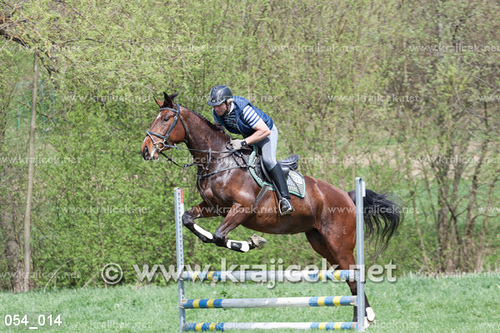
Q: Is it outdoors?
A: Yes, it is outdoors.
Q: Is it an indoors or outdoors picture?
A: It is outdoors.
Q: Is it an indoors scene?
A: No, it is outdoors.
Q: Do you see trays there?
A: No, there are no trays.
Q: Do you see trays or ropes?
A: No, there are no trays or ropes.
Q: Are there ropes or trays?
A: No, there are no trays or ropes.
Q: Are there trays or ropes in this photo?
A: No, there are no trays or ropes.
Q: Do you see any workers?
A: No, there are no workers.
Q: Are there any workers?
A: No, there are no workers.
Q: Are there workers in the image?
A: No, there are no workers.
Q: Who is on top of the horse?
A: The man is on top of the horse.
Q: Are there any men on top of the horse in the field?
A: Yes, there is a man on top of the horse.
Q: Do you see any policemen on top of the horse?
A: No, there is a man on top of the horse.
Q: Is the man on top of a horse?
A: Yes, the man is on top of a horse.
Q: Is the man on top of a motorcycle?
A: No, the man is on top of a horse.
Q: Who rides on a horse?
A: The man rides on a horse.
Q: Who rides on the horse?
A: The man rides on a horse.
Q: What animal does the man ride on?
A: The man rides on a horse.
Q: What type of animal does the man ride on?
A: The man rides on a horse.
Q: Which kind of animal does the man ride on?
A: The man rides on a horse.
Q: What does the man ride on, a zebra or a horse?
A: The man rides on a horse.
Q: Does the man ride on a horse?
A: Yes, the man rides on a horse.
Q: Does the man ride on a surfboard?
A: No, the man rides on a horse.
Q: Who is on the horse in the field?
A: The man is on the horse.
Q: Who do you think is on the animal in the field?
A: The man is on the horse.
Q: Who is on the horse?
A: The man is on the horse.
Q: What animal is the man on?
A: The man is on the horse.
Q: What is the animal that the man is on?
A: The animal is a horse.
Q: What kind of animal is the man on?
A: The man is on the horse.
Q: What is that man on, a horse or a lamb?
A: The man is on a horse.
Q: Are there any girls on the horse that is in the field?
A: No, there is a man on the horse.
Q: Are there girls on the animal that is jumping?
A: No, there is a man on the horse.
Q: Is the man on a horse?
A: Yes, the man is on a horse.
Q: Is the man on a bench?
A: No, the man is on a horse.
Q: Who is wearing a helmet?
A: The man is wearing a helmet.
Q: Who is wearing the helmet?
A: The man is wearing a helmet.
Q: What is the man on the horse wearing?
A: The man is wearing a helmet.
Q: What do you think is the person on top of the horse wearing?
A: The man is wearing a helmet.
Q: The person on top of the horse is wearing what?
A: The man is wearing a helmet.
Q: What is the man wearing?
A: The man is wearing a helmet.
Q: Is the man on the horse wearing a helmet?
A: Yes, the man is wearing a helmet.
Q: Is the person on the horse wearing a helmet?
A: Yes, the man is wearing a helmet.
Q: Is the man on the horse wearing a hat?
A: No, the man is wearing a helmet.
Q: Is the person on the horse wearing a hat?
A: No, the man is wearing a helmet.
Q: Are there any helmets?
A: Yes, there is a helmet.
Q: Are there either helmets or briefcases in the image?
A: Yes, there is a helmet.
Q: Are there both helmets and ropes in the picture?
A: No, there is a helmet but no ropes.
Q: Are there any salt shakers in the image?
A: No, there are no salt shakers.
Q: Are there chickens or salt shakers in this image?
A: No, there are no salt shakers or chickens.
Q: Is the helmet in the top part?
A: Yes, the helmet is in the top of the image.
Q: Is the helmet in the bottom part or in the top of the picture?
A: The helmet is in the top of the image.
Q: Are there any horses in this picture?
A: Yes, there is a horse.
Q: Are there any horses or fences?
A: Yes, there is a horse.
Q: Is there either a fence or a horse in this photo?
A: Yes, there is a horse.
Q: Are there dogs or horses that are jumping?
A: Yes, the horse is jumping.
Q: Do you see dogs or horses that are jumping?
A: Yes, the horse is jumping.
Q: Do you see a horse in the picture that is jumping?
A: Yes, there is a horse that is jumping.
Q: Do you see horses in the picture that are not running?
A: Yes, there is a horse that is jumping .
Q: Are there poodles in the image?
A: No, there are no poodles.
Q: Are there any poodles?
A: No, there are no poodles.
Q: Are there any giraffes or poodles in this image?
A: No, there are no poodles or giraffes.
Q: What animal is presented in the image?
A: The animal is a horse.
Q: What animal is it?
A: The animal is a horse.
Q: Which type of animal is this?
A: This is a horse.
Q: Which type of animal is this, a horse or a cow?
A: This is a horse.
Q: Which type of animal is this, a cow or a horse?
A: This is a horse.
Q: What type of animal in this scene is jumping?
A: The animal is a horse.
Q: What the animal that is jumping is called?
A: The animal is a horse.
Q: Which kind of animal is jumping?
A: The animal is a horse.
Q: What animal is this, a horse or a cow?
A: This is a horse.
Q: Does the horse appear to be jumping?
A: Yes, the horse is jumping.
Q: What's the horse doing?
A: The horse is jumping.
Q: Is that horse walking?
A: No, the horse is jumping.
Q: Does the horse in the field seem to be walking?
A: No, the horse is jumping.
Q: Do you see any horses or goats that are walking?
A: No, there is a horse but it is jumping.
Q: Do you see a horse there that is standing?
A: No, there is a horse but it is jumping.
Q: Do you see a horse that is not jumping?
A: No, there is a horse but it is jumping.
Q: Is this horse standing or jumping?
A: The horse is jumping.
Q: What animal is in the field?
A: The horse is in the field.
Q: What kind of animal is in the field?
A: The animal is a horse.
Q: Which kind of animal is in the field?
A: The animal is a horse.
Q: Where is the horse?
A: The horse is in the field.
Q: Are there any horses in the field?
A: Yes, there is a horse in the field.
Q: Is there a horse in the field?
A: Yes, there is a horse in the field.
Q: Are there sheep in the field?
A: No, there is a horse in the field.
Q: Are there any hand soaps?
A: No, there are no hand soaps.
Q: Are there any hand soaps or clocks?
A: No, there are no hand soaps or clocks.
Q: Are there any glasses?
A: No, there are no glasses.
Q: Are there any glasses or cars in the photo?
A: No, there are no glasses or cars.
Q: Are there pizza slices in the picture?
A: No, there are no pizza slices.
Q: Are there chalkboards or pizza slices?
A: No, there are no pizza slices or chalkboards.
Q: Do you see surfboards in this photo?
A: No, there are no surfboards.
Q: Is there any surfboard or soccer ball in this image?
A: No, there are no surfboards or soccer balls.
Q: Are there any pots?
A: No, there are no pots.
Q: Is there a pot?
A: No, there are no pots.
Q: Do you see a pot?
A: No, there are no pots.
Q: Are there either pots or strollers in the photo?
A: No, there are no pots or strollers.